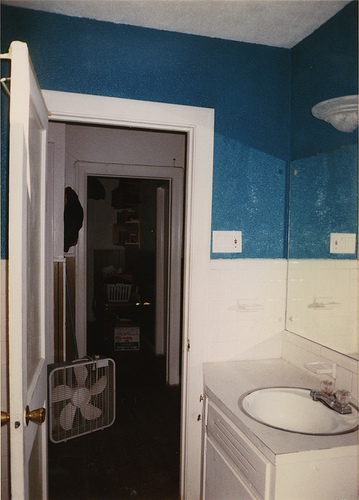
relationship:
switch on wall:
[167, 207, 250, 290] [167, 169, 287, 323]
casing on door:
[77, 147, 172, 190] [6, 104, 69, 371]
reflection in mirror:
[308, 82, 348, 124] [243, 192, 349, 360]